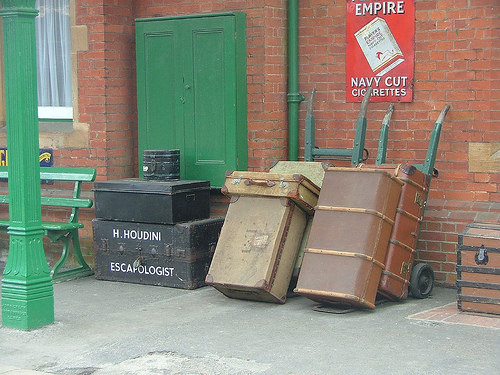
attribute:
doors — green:
[131, 19, 242, 180]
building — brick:
[39, 5, 498, 294]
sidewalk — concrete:
[2, 264, 497, 373]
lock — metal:
[476, 247, 485, 261]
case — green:
[455, 220, 498, 315]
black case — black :
[87, 218, 223, 290]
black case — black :
[89, 176, 213, 221]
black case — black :
[133, 145, 182, 182]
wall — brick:
[1, 1, 497, 286]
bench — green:
[40, 169, 101, 261]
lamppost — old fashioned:
[6, 0, 67, 330]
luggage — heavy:
[291, 163, 436, 315]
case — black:
[85, 171, 210, 227]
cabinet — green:
[129, 9, 245, 190]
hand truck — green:
[377, 98, 457, 163]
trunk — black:
[80, 215, 207, 290]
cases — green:
[311, 132, 423, 298]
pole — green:
[2, 0, 62, 335]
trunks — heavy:
[288, 82, 458, 309]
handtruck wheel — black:
[410, 261, 434, 298]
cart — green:
[343, 97, 456, 302]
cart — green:
[277, 80, 379, 298]